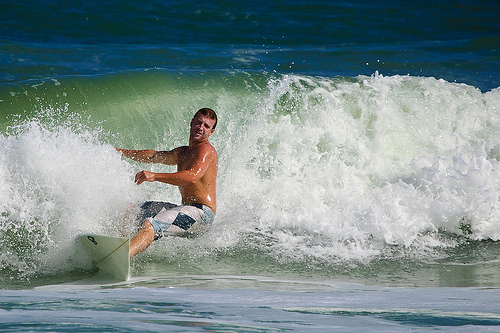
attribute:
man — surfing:
[116, 109, 251, 249]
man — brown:
[115, 97, 230, 263]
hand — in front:
[134, 166, 157, 188]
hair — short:
[191, 97, 221, 121]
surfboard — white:
[57, 223, 132, 287]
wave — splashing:
[32, 81, 323, 285]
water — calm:
[2, 245, 498, 331]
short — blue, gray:
[137, 200, 215, 242]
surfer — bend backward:
[141, 102, 253, 242]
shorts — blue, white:
[135, 200, 220, 242]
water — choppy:
[1, 1, 498, 331]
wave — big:
[0, 56, 498, 262]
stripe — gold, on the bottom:
[91, 234, 127, 265]